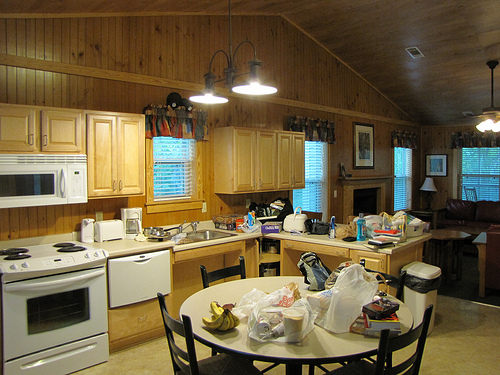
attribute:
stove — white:
[1, 233, 111, 372]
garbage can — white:
[403, 262, 441, 329]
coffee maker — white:
[121, 206, 145, 243]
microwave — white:
[3, 164, 87, 210]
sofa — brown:
[436, 197, 499, 246]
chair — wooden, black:
[158, 294, 258, 372]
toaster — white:
[95, 218, 126, 244]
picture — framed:
[352, 123, 375, 170]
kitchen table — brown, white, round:
[181, 276, 414, 374]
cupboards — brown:
[212, 124, 305, 194]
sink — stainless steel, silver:
[178, 229, 237, 245]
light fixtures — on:
[189, 2, 278, 107]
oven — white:
[4, 270, 107, 369]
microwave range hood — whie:
[0, 154, 87, 165]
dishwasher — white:
[108, 251, 171, 312]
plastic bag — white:
[245, 283, 316, 343]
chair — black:
[333, 306, 434, 373]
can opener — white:
[80, 219, 94, 243]